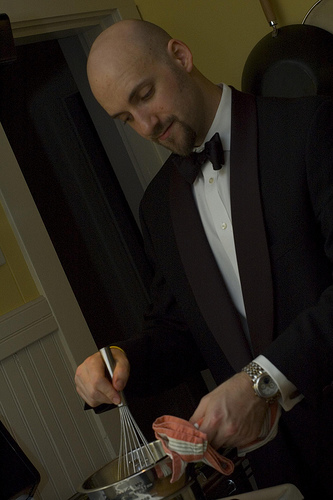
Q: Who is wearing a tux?
A: The man.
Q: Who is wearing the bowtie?
A: The man.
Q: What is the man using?
A: Whisk.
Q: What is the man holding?
A: Towel.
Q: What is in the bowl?
A: Whisk.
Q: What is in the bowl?
A: Whisk.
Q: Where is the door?
A: On the left.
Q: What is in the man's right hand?
A: A whisk.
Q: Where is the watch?
A: On the man's left hand.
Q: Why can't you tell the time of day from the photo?
A: No windows shown.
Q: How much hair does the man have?
A: He is bald.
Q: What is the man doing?
A: Mixing ingredients.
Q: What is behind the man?
A: A yellow wall.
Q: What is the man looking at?
A: The mixing bowl.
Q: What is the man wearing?
A: A tuxedo.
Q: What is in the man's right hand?
A: A metal whisk.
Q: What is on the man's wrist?
A: A watch.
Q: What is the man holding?
A: A dishrag.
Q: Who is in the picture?
A: A man.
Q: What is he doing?
A: Preparing food.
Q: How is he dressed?
A: In a tuxedo.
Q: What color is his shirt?
A: White.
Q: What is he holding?
A: A pan.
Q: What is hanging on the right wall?
A: A pan.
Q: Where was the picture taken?
A: A kitchen.